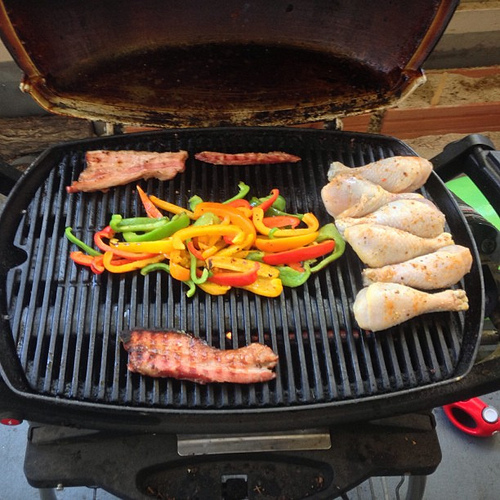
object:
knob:
[221, 475, 250, 498]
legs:
[321, 156, 472, 333]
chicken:
[327, 156, 433, 194]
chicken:
[319, 175, 425, 217]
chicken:
[334, 197, 446, 242]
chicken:
[343, 223, 457, 267]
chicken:
[361, 245, 472, 290]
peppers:
[64, 182, 345, 298]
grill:
[7, 130, 468, 411]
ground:
[243, 196, 268, 218]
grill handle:
[0, 158, 24, 422]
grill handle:
[428, 130, 500, 393]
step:
[419, 102, 500, 138]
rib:
[118, 328, 279, 384]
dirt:
[398, 74, 500, 109]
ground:
[430, 106, 457, 131]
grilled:
[62, 147, 303, 388]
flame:
[226, 332, 232, 339]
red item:
[442, 397, 500, 437]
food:
[65, 182, 344, 298]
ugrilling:
[118, 327, 279, 382]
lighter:
[442, 396, 500, 438]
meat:
[118, 327, 278, 383]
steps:
[400, 0, 500, 142]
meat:
[320, 156, 472, 330]